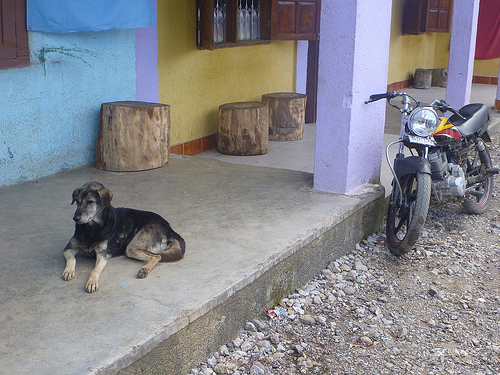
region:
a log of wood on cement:
[98, 100, 170, 168]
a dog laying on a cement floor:
[61, 180, 187, 292]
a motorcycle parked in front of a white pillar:
[359, 90, 497, 256]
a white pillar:
[312, 3, 392, 195]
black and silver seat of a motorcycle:
[450, 103, 491, 135]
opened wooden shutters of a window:
[196, 0, 323, 44]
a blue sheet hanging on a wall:
[28, 0, 156, 32]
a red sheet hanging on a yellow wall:
[447, 0, 499, 59]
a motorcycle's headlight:
[407, 105, 439, 138]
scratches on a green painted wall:
[36, 43, 104, 75]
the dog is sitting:
[73, 227, 157, 277]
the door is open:
[260, 3, 305, 34]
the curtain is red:
[484, 14, 494, 36]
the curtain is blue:
[83, 7, 111, 24]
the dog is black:
[116, 209, 132, 221]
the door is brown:
[280, 13, 307, 30]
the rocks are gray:
[309, 281, 345, 301]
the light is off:
[416, 115, 435, 132]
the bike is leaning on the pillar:
[357, 86, 432, 146]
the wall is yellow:
[181, 61, 221, 93]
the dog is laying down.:
[55, 183, 185, 287]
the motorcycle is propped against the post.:
[371, 88, 498, 253]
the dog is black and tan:
[56, 182, 185, 284]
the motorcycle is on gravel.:
[367, 81, 497, 259]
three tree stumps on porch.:
[98, 92, 310, 169]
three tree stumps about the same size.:
[93, 90, 310, 169]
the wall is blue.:
[3, 30, 165, 182]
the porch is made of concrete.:
[1, 163, 327, 368]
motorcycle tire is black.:
[382, 155, 433, 255]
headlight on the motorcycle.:
[407, 103, 437, 140]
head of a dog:
[66, 182, 107, 234]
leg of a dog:
[56, 233, 88, 288]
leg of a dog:
[88, 253, 114, 310]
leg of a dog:
[125, 234, 165, 276]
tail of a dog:
[160, 231, 187, 266]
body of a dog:
[115, 205, 171, 247]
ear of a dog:
[95, 185, 119, 203]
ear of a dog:
[68, 188, 80, 208]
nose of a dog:
[66, 214, 85, 229]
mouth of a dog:
[75, 215, 100, 223]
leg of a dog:
[78, 245, 110, 299]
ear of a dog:
[63, 186, 84, 213]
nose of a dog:
[71, 213, 84, 221]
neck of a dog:
[96, 198, 113, 228]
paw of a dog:
[54, 265, 83, 285]